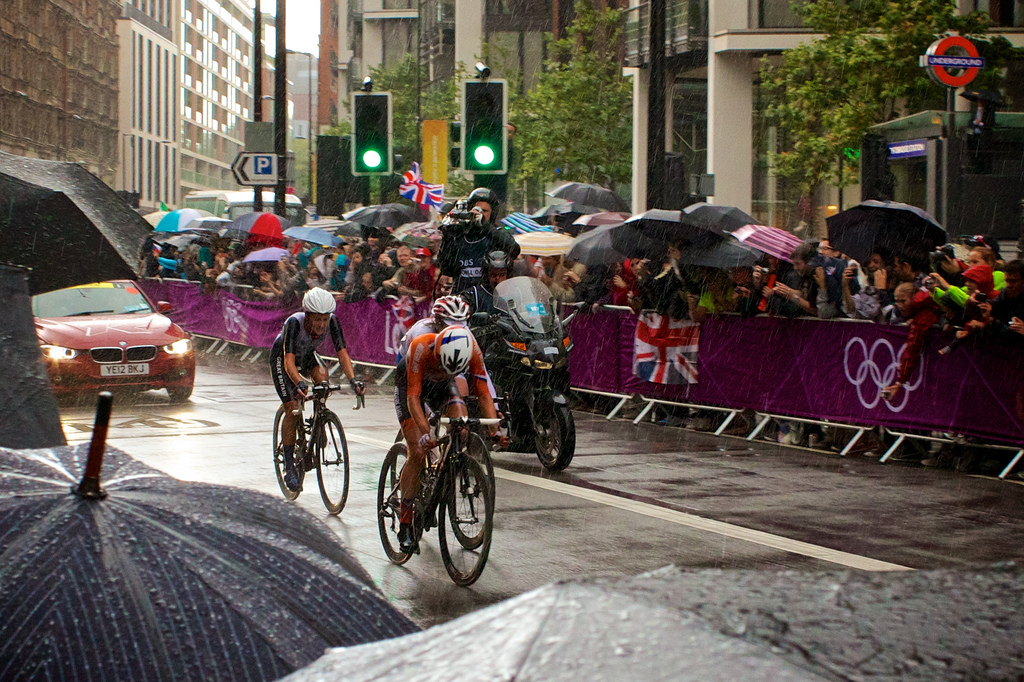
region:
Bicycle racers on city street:
[251, 264, 507, 594]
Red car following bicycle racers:
[20, 264, 201, 407]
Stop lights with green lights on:
[332, 62, 517, 195]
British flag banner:
[617, 295, 709, 400]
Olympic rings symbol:
[832, 321, 932, 423]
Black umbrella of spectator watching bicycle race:
[1, 371, 419, 676]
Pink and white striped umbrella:
[721, 207, 810, 268]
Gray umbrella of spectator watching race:
[269, 566, 830, 674]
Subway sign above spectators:
[905, 16, 983, 94]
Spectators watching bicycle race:
[153, 184, 1004, 336]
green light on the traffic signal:
[352, 141, 397, 171]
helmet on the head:
[285, 282, 337, 341]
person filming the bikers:
[425, 184, 527, 277]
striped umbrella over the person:
[732, 212, 809, 273]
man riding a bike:
[362, 315, 512, 581]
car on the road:
[29, 275, 204, 406]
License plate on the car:
[92, 354, 153, 381]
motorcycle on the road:
[465, 274, 599, 467]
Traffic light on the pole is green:
[326, 63, 527, 206]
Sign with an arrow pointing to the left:
[226, 135, 344, 219]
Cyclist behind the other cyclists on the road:
[245, 263, 370, 548]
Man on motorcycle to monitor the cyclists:
[428, 228, 643, 489]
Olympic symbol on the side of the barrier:
[829, 307, 938, 448]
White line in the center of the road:
[377, 405, 988, 601]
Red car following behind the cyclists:
[30, 260, 190, 420]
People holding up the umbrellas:
[35, 341, 928, 675]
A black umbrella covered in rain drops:
[4, 393, 426, 681]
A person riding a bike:
[373, 325, 492, 588]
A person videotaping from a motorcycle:
[434, 186, 578, 472]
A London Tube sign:
[913, 37, 986, 89]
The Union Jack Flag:
[630, 311, 697, 387]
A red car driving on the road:
[32, 280, 195, 407]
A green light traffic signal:
[461, 75, 504, 177]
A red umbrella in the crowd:
[737, 226, 804, 261]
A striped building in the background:
[112, 1, 180, 211]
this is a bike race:
[29, 31, 941, 572]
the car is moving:
[49, 262, 221, 431]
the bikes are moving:
[283, 277, 727, 645]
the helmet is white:
[412, 320, 587, 495]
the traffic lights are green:
[342, 127, 611, 223]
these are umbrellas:
[23, 426, 725, 680]